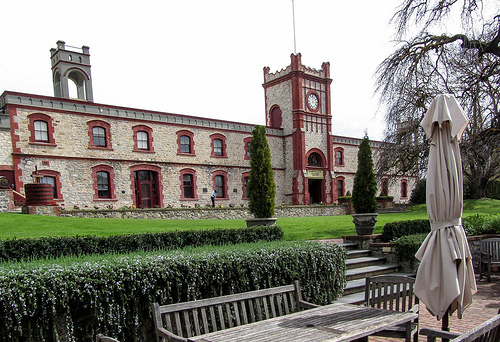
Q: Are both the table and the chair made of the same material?
A: Yes, both the table and the chair are made of wood.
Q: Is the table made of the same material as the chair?
A: Yes, both the table and the chair are made of wood.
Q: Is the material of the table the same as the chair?
A: Yes, both the table and the chair are made of wood.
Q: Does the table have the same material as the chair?
A: Yes, both the table and the chair are made of wood.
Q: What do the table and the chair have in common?
A: The material, both the table and the chair are wooden.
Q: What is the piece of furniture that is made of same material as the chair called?
A: The piece of furniture is a table.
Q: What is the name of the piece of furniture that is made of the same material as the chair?
A: The piece of furniture is a table.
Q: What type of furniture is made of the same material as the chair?
A: The table is made of the same material as the chair.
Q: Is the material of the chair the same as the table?
A: Yes, both the chair and the table are made of wood.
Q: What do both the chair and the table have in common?
A: The material, both the chair and the table are wooden.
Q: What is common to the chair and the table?
A: The material, both the chair and the table are wooden.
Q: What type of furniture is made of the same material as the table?
A: The chair is made of the same material as the table.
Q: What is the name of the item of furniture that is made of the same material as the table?
A: The piece of furniture is a chair.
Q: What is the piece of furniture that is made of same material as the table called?
A: The piece of furniture is a chair.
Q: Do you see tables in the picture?
A: Yes, there is a table.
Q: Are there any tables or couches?
A: Yes, there is a table.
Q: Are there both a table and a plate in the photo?
A: No, there is a table but no plates.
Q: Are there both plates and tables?
A: No, there is a table but no plates.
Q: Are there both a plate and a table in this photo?
A: No, there is a table but no plates.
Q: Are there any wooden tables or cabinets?
A: Yes, there is a wood table.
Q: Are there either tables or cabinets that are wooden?
A: Yes, the table is wooden.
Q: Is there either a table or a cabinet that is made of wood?
A: Yes, the table is made of wood.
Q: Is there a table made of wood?
A: Yes, there is a table that is made of wood.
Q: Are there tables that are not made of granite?
A: Yes, there is a table that is made of wood.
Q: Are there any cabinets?
A: No, there are no cabinets.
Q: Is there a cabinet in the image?
A: No, there are no cabinets.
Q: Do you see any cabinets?
A: No, there are no cabinets.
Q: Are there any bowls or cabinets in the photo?
A: No, there are no cabinets or bowls.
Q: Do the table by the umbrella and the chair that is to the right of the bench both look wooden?
A: Yes, both the table and the chair are wooden.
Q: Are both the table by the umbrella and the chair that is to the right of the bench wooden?
A: Yes, both the table and the chair are wooden.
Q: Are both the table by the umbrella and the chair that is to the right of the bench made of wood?
A: Yes, both the table and the chair are made of wood.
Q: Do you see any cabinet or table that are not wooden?
A: No, there is a table but it is wooden.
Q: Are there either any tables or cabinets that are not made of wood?
A: No, there is a table but it is made of wood.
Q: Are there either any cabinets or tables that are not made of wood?
A: No, there is a table but it is made of wood.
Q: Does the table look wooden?
A: Yes, the table is wooden.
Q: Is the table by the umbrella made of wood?
A: Yes, the table is made of wood.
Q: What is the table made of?
A: The table is made of wood.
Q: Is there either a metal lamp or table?
A: No, there is a table but it is wooden.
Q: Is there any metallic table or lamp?
A: No, there is a table but it is wooden.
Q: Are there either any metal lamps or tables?
A: No, there is a table but it is wooden.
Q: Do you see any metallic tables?
A: No, there is a table but it is wooden.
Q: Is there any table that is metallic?
A: No, there is a table but it is wooden.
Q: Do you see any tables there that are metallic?
A: No, there is a table but it is wooden.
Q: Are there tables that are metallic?
A: No, there is a table but it is wooden.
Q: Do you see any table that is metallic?
A: No, there is a table but it is wooden.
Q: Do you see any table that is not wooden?
A: No, there is a table but it is wooden.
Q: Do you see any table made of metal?
A: No, there is a table but it is made of wood.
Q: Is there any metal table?
A: No, there is a table but it is made of wood.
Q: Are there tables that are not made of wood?
A: No, there is a table but it is made of wood.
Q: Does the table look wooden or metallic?
A: The table is wooden.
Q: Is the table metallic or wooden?
A: The table is wooden.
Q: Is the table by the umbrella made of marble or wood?
A: The table is made of wood.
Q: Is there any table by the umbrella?
A: Yes, there is a table by the umbrella.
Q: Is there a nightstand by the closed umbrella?
A: No, there is a table by the umbrella.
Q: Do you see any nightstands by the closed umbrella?
A: No, there is a table by the umbrella.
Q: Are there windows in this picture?
A: Yes, there is a window.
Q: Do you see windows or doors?
A: Yes, there is a window.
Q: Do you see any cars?
A: No, there are no cars.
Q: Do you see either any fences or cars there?
A: No, there are no cars or fences.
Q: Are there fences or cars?
A: No, there are no cars or fences.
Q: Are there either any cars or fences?
A: No, there are no cars or fences.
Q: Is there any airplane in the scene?
A: No, there are no airplanes.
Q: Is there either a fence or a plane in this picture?
A: No, there are no airplanes or fences.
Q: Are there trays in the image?
A: No, there are no trays.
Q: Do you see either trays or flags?
A: No, there are no trays or flags.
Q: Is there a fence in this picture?
A: No, there are no fences.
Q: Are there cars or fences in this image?
A: No, there are no fences or cars.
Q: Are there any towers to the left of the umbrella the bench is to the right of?
A: Yes, there is a tower to the left of the umbrella.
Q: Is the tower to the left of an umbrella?
A: Yes, the tower is to the left of an umbrella.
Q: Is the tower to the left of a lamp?
A: No, the tower is to the left of an umbrella.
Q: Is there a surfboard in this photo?
A: No, there are no surfboards.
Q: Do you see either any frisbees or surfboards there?
A: No, there are no surfboards or frisbees.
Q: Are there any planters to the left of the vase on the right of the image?
A: Yes, there is a planter to the left of the vase.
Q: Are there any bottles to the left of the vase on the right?
A: No, there is a planter to the left of the vase.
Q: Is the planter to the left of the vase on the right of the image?
A: Yes, the planter is to the left of the vase.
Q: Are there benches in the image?
A: Yes, there is a bench.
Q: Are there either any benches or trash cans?
A: Yes, there is a bench.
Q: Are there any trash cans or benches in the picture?
A: Yes, there is a bench.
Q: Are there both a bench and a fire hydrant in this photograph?
A: No, there is a bench but no fire hydrants.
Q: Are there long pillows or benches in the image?
A: Yes, there is a long bench.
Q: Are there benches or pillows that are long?
A: Yes, the bench is long.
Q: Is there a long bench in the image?
A: Yes, there is a long bench.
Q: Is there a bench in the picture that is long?
A: Yes, there is a bench that is long.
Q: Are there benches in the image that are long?
A: Yes, there is a bench that is long.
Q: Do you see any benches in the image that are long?
A: Yes, there is a bench that is long.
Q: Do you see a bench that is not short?
A: Yes, there is a long bench.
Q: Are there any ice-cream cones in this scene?
A: No, there are no ice-cream cones.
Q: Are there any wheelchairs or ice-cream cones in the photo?
A: No, there are no ice-cream cones or wheelchairs.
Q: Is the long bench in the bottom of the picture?
A: Yes, the bench is in the bottom of the image.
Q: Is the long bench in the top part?
A: No, the bench is in the bottom of the image.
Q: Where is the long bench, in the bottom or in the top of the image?
A: The bench is in the bottom of the image.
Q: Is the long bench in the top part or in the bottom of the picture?
A: The bench is in the bottom of the image.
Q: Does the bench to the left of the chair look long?
A: Yes, the bench is long.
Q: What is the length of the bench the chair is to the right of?
A: The bench is long.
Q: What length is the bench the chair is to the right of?
A: The bench is long.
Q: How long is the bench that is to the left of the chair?
A: The bench is long.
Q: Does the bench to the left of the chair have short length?
A: No, the bench is long.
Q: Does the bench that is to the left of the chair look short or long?
A: The bench is long.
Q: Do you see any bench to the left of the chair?
A: Yes, there is a bench to the left of the chair.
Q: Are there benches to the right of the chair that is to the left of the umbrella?
A: No, the bench is to the left of the chair.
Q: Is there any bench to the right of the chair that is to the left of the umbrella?
A: No, the bench is to the left of the chair.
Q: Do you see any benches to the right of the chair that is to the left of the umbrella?
A: No, the bench is to the left of the chair.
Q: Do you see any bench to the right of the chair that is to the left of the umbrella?
A: No, the bench is to the left of the chair.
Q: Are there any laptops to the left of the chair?
A: No, there is a bench to the left of the chair.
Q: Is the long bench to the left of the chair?
A: Yes, the bench is to the left of the chair.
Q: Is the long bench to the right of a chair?
A: No, the bench is to the left of a chair.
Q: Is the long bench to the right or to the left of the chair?
A: The bench is to the left of the chair.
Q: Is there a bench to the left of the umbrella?
A: Yes, there is a bench to the left of the umbrella.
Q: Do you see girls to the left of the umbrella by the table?
A: No, there is a bench to the left of the umbrella.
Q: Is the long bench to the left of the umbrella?
A: Yes, the bench is to the left of the umbrella.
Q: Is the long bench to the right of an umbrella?
A: No, the bench is to the left of an umbrella.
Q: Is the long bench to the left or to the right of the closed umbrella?
A: The bench is to the left of the umbrella.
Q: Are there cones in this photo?
A: No, there are no cones.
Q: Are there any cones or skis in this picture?
A: No, there are no cones or skis.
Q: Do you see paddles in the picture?
A: No, there are no paddles.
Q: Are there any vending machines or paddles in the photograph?
A: No, there are no paddles or vending machines.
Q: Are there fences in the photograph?
A: No, there are no fences.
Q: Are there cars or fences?
A: No, there are no fences or cars.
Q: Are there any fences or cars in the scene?
A: No, there are no fences or cars.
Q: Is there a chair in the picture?
A: Yes, there is a chair.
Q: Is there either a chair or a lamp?
A: Yes, there is a chair.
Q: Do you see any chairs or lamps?
A: Yes, there is a chair.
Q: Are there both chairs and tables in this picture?
A: Yes, there are both a chair and a table.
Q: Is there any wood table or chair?
A: Yes, there is a wood chair.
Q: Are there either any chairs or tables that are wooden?
A: Yes, the chair is wooden.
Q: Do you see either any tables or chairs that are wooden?
A: Yes, the chair is wooden.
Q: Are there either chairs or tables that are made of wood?
A: Yes, the chair is made of wood.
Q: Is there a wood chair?
A: Yes, there is a chair that is made of wood.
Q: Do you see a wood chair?
A: Yes, there is a chair that is made of wood.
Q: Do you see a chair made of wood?
A: Yes, there is a chair that is made of wood.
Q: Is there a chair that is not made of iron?
A: Yes, there is a chair that is made of wood.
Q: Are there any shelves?
A: No, there are no shelves.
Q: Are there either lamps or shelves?
A: No, there are no shelves or lamps.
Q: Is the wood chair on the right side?
A: Yes, the chair is on the right of the image.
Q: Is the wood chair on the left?
A: No, the chair is on the right of the image.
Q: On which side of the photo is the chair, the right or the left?
A: The chair is on the right of the image.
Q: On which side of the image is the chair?
A: The chair is on the right of the image.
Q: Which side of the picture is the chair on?
A: The chair is on the right of the image.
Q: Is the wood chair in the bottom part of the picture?
A: Yes, the chair is in the bottom of the image.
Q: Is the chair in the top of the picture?
A: No, the chair is in the bottom of the image.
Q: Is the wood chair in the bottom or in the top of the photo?
A: The chair is in the bottom of the image.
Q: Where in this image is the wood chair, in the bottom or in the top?
A: The chair is in the bottom of the image.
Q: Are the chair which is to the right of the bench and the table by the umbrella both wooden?
A: Yes, both the chair and the table are wooden.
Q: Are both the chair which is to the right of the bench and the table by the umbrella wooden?
A: Yes, both the chair and the table are wooden.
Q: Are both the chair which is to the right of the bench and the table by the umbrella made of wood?
A: Yes, both the chair and the table are made of wood.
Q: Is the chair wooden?
A: Yes, the chair is wooden.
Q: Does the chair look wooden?
A: Yes, the chair is wooden.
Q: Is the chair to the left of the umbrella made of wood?
A: Yes, the chair is made of wood.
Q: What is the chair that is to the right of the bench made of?
A: The chair is made of wood.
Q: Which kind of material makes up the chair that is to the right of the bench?
A: The chair is made of wood.